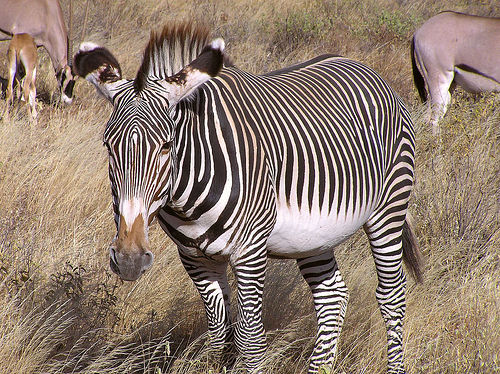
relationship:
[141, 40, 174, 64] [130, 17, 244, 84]
hairs sticking hairs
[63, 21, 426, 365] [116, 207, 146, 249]
animal has spot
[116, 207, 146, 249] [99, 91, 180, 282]
spot in face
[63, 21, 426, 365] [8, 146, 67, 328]
animal standing grass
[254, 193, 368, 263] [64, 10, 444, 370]
belly of zebra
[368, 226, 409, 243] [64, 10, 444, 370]
strip on zebra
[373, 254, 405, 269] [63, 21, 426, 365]
strip on animal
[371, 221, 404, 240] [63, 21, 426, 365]
strip on animal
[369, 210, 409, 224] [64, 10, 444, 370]
strip on zebra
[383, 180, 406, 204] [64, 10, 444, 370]
strip on zebra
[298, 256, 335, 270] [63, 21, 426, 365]
strip on animal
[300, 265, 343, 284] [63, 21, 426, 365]
strip on animal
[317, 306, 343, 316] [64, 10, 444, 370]
strip on zebra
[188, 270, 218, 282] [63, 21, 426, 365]
strip on animal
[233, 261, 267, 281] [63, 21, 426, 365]
strip on animal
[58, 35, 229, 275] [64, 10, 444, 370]
head of a zebra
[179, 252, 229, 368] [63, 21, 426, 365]
leg of a animal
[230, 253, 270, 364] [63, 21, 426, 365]
leg of a animal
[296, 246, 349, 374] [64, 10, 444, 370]
hind leg of a zebra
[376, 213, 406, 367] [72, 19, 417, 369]
leg of a zebra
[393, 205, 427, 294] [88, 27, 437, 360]
tail of a zebra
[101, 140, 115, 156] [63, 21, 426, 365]
eye of a animal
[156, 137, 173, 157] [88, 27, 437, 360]
eye of a zebra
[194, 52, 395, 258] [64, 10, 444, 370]
body of a zebra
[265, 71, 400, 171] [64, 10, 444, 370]
skin of a zebra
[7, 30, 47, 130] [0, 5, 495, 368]
animal standing in forest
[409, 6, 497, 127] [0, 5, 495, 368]
animal standing in forest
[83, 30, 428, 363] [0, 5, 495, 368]
animal standing in forest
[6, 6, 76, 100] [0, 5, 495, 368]
animal standing in forest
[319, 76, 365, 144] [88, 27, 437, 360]
stripe of zebra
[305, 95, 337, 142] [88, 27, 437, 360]
stripe of zebra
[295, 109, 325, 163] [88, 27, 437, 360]
stripe of zebra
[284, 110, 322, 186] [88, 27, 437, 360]
stripe of zebra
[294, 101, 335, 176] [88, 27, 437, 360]
stripe of zebra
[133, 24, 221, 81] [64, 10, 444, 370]
mane of zebra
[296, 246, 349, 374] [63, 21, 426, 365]
hind leg of animal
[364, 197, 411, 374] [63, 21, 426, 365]
hind leg of animal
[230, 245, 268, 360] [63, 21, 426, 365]
leg of animal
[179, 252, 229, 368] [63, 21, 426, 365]
leg of animal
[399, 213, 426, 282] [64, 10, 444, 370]
tail of zebra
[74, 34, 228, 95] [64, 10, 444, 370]
ears of zebra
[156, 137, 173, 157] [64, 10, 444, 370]
eye of zebra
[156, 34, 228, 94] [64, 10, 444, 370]
ear of zebra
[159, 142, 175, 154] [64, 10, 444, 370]
eye of zebra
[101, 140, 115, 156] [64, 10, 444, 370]
eye of zebra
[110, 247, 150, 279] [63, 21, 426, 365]
nose of animal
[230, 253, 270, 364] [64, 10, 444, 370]
leg of zebra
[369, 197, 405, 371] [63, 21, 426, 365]
hind leg of animal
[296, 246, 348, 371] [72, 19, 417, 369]
hind leg of zebra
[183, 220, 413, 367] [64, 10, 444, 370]
legs on zebra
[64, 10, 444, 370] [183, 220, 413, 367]
zebra has legs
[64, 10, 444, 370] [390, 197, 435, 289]
zebra has tail